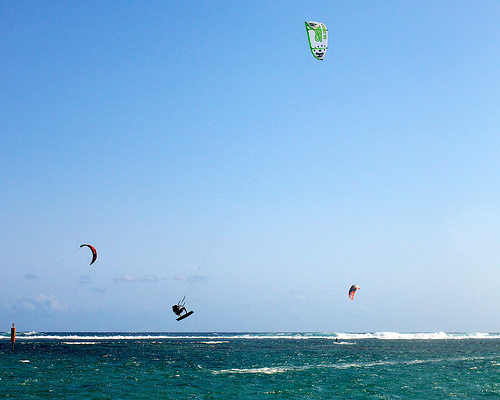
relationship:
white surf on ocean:
[350, 332, 496, 342] [109, 342, 327, 389]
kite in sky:
[299, 14, 343, 62] [0, 3, 490, 330]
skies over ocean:
[5, 35, 490, 347] [0, 332, 498, 399]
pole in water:
[11, 322, 18, 344] [6, 332, 496, 396]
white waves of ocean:
[0, 332, 497, 344] [0, 332, 498, 399]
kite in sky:
[303, 19, 333, 77] [0, 3, 490, 330]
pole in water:
[8, 324, 22, 347] [228, 353, 373, 378]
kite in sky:
[81, 19, 360, 302] [0, 3, 490, 330]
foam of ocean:
[7, 333, 454, 341] [11, 314, 494, 390]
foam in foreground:
[213, 354, 496, 369] [0, 336, 496, 397]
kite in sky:
[346, 283, 359, 301] [0, 3, 490, 330]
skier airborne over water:
[170, 303, 188, 317] [0, 328, 499, 398]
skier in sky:
[166, 293, 199, 322] [0, 3, 490, 330]